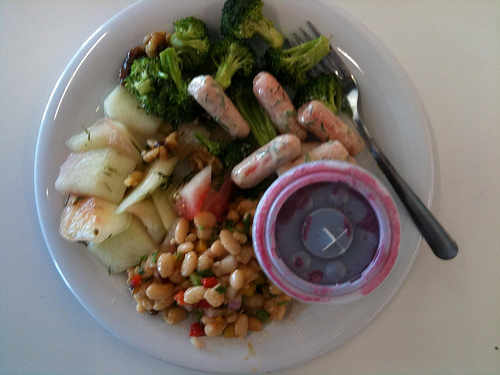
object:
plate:
[32, 0, 436, 375]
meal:
[58, 0, 404, 350]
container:
[253, 161, 402, 306]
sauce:
[253, 159, 403, 306]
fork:
[286, 18, 458, 262]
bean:
[175, 216, 190, 244]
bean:
[182, 249, 196, 277]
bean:
[157, 251, 176, 279]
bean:
[184, 285, 207, 305]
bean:
[230, 267, 245, 292]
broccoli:
[221, 0, 286, 51]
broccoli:
[169, 15, 211, 65]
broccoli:
[209, 39, 257, 90]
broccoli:
[267, 37, 329, 83]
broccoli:
[295, 74, 340, 112]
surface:
[0, 0, 499, 375]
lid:
[252, 159, 403, 304]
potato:
[104, 85, 164, 134]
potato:
[65, 116, 149, 167]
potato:
[53, 147, 137, 204]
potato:
[56, 192, 131, 247]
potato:
[88, 223, 157, 276]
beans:
[183, 284, 205, 302]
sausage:
[189, 71, 251, 140]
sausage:
[253, 70, 310, 141]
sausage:
[232, 129, 304, 189]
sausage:
[298, 98, 367, 158]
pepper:
[202, 276, 217, 289]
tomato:
[188, 322, 210, 338]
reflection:
[50, 31, 115, 123]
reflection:
[335, 44, 368, 74]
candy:
[142, 32, 168, 57]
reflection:
[343, 85, 361, 122]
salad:
[55, 84, 228, 271]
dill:
[83, 124, 93, 142]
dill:
[102, 181, 114, 194]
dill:
[103, 165, 117, 176]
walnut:
[118, 47, 144, 80]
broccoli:
[122, 55, 166, 100]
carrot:
[117, 157, 179, 211]